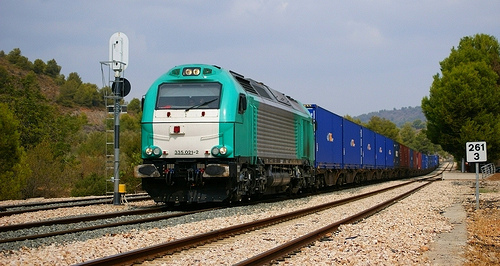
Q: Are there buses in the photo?
A: No, there are no buses.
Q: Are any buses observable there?
A: No, there are no buses.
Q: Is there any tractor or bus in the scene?
A: No, there are no buses or tractors.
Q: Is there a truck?
A: No, there are no trucks.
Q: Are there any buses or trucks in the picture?
A: No, there are no trucks or buses.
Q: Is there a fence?
A: No, there are no fences.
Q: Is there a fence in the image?
A: No, there are no fences.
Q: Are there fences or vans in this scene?
A: No, there are no fences or vans.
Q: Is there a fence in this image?
A: No, there are no fences.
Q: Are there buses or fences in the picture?
A: No, there are no fences or buses.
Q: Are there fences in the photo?
A: No, there are no fences.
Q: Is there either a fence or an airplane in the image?
A: No, there are no fences or airplanes.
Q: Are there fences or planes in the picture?
A: No, there are no fences or planes.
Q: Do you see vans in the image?
A: No, there are no vans.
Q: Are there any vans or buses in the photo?
A: No, there are no vans or buses.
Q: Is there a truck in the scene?
A: No, there are no trucks.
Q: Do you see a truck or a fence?
A: No, there are no trucks or fences.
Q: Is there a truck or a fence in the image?
A: No, there are no trucks or fences.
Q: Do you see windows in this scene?
A: Yes, there is a window.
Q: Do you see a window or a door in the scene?
A: Yes, there is a window.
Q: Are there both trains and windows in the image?
A: Yes, there are both a window and a train.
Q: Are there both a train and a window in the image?
A: Yes, there are both a window and a train.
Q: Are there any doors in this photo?
A: No, there are no doors.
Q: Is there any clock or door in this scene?
A: No, there are no doors or clocks.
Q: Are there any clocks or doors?
A: No, there are no doors or clocks.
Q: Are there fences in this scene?
A: No, there are no fences.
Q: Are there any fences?
A: No, there are no fences.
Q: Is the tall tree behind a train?
A: Yes, the tree is behind a train.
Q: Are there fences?
A: No, there are no fences.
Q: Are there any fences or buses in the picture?
A: No, there are no fences or buses.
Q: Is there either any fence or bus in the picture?
A: No, there are no fences or buses.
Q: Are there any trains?
A: Yes, there is a train.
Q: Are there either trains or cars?
A: Yes, there is a train.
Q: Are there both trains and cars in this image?
A: Yes, there are both a train and a car.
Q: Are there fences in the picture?
A: No, there are no fences.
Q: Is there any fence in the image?
A: No, there are no fences.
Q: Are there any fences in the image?
A: No, there are no fences.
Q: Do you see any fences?
A: No, there are no fences.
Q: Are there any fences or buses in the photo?
A: No, there are no fences or buses.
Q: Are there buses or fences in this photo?
A: No, there are no fences or buses.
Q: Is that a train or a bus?
A: That is a train.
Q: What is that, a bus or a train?
A: That is a train.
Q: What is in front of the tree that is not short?
A: The train is in front of the tree.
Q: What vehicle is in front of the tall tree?
A: The vehicle is a train.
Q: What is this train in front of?
A: The train is in front of the tree.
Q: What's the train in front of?
A: The train is in front of the tree.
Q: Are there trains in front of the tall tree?
A: Yes, there is a train in front of the tree.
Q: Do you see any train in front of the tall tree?
A: Yes, there is a train in front of the tree.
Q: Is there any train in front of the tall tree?
A: Yes, there is a train in front of the tree.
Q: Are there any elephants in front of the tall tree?
A: No, there is a train in front of the tree.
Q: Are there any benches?
A: No, there are no benches.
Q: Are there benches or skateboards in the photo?
A: No, there are no benches or skateboards.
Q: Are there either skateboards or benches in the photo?
A: No, there are no benches or skateboards.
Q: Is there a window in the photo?
A: Yes, there is a window.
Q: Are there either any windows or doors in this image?
A: Yes, there is a window.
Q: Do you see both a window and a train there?
A: Yes, there are both a window and a train.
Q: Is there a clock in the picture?
A: No, there are no clocks.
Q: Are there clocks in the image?
A: No, there are no clocks.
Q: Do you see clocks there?
A: No, there are no clocks.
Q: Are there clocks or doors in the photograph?
A: No, there are no clocks or doors.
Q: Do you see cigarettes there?
A: No, there are no cigarettes.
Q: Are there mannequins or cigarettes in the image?
A: No, there are no cigarettes or mannequins.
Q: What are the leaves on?
A: The leaves are on the tree.